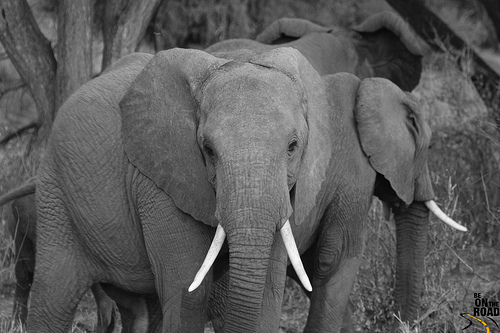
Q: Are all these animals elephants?
A: Yes, all the animals are elephants.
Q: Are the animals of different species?
A: No, all the animals are elephants.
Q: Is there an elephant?
A: Yes, there is an elephant.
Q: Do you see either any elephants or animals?
A: Yes, there is an elephant.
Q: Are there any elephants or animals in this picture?
A: Yes, there is an elephant.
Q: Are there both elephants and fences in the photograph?
A: No, there is an elephant but no fences.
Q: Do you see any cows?
A: No, there are no cows.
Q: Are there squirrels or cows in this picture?
A: No, there are no cows or squirrels.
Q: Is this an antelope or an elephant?
A: This is an elephant.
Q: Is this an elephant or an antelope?
A: This is an elephant.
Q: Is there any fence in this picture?
A: No, there are no fences.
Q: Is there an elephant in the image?
A: Yes, there is an elephant.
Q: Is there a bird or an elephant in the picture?
A: Yes, there is an elephant.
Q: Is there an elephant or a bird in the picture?
A: Yes, there is an elephant.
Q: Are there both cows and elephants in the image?
A: No, there is an elephant but no cows.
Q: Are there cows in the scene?
A: No, there are no cows.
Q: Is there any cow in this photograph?
A: No, there are no cows.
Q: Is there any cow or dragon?
A: No, there are no cows or dragons.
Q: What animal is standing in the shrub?
A: The elephant is standing in the shrub.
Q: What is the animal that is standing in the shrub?
A: The animal is an elephant.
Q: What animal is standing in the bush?
A: The animal is an elephant.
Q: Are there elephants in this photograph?
A: Yes, there is an elephant.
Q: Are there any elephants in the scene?
A: Yes, there is an elephant.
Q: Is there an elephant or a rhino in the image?
A: Yes, there is an elephant.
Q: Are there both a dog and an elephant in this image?
A: No, there is an elephant but no dogs.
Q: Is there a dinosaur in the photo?
A: No, there are no dinosaurs.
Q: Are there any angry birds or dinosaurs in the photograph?
A: No, there are no dinosaurs or angry birds.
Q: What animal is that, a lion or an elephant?
A: That is an elephant.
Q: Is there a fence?
A: No, there are no fences.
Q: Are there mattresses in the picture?
A: No, there are no mattresses.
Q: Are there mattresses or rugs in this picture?
A: No, there are no mattresses or rugs.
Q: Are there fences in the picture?
A: No, there are no fences.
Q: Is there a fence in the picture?
A: No, there are no fences.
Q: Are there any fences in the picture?
A: No, there are no fences.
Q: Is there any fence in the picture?
A: No, there are no fences.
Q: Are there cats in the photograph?
A: No, there are no cats.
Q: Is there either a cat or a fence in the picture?
A: No, there are no cats or fences.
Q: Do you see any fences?
A: No, there are no fences.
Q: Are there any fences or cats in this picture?
A: No, there are no fences or cats.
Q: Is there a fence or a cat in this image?
A: No, there are no fences or cats.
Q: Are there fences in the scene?
A: No, there are no fences.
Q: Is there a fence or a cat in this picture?
A: No, there are no fences or cats.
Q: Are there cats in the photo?
A: No, there are no cats.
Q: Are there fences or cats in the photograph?
A: No, there are no cats or fences.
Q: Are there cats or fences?
A: No, there are no cats or fences.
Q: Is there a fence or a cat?
A: No, there are no fences or cats.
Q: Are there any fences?
A: No, there are no fences.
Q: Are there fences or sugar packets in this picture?
A: No, there are no fences or sugar packets.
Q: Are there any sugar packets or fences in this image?
A: No, there are no fences or sugar packets.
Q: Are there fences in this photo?
A: No, there are no fences.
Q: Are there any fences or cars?
A: No, there are no fences or cars.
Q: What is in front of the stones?
A: The tree is in front of the stones.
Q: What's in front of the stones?
A: The tree is in front of the stones.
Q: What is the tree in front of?
A: The tree is in front of the stones.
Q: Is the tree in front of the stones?
A: Yes, the tree is in front of the stones.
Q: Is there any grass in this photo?
A: Yes, there is grass.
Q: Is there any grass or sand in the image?
A: Yes, there is grass.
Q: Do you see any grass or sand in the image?
A: Yes, there is grass.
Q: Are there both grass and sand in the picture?
A: No, there is grass but no sand.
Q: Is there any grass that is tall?
A: Yes, there is tall grass.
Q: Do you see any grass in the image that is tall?
A: Yes, there is grass that is tall.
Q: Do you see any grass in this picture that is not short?
A: Yes, there is tall grass.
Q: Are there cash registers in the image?
A: No, there are no cash registers.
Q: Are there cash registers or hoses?
A: No, there are no cash registers or hoses.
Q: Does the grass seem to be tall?
A: Yes, the grass is tall.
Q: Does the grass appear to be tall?
A: Yes, the grass is tall.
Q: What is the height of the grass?
A: The grass is tall.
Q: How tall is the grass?
A: The grass is tall.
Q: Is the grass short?
A: No, the grass is tall.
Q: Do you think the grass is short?
A: No, the grass is tall.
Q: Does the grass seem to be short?
A: No, the grass is tall.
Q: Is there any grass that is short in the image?
A: No, there is grass but it is tall.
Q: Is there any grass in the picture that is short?
A: No, there is grass but it is tall.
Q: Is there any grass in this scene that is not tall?
A: No, there is grass but it is tall.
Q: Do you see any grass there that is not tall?
A: No, there is grass but it is tall.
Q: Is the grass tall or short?
A: The grass is tall.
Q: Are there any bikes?
A: No, there are no bikes.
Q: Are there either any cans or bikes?
A: No, there are no bikes or cans.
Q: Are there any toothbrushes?
A: No, there are no toothbrushes.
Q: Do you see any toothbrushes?
A: No, there are no toothbrushes.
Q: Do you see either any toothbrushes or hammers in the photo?
A: No, there are no toothbrushes or hammers.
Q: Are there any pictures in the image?
A: No, there are no pictures.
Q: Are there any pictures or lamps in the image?
A: No, there are no pictures or lamps.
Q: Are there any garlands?
A: No, there are no garlands.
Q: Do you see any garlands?
A: No, there are no garlands.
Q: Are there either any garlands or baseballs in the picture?
A: No, there are no garlands or baseballs.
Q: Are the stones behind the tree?
A: Yes, the stones are behind the tree.